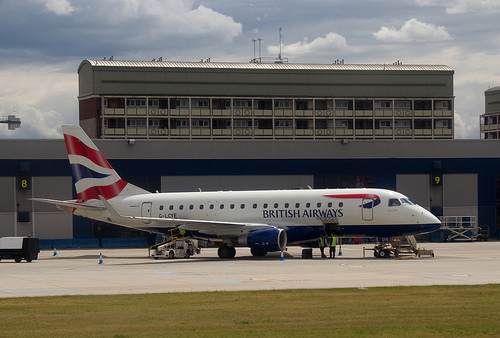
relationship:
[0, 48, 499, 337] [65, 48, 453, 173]
airport at airport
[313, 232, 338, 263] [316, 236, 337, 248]
men wearing vest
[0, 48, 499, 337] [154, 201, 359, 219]
airport has windows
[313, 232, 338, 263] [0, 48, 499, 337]
men under airport